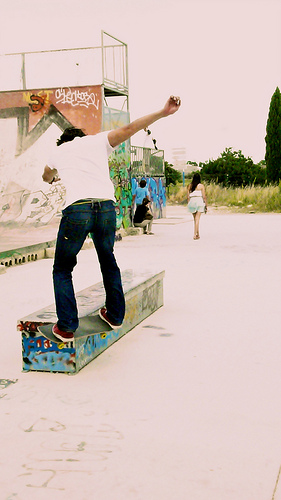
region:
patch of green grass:
[243, 194, 255, 205]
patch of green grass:
[214, 185, 230, 199]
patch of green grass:
[220, 179, 235, 188]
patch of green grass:
[216, 191, 224, 202]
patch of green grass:
[169, 190, 175, 202]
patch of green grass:
[232, 198, 238, 206]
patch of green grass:
[172, 190, 177, 198]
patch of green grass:
[244, 192, 254, 202]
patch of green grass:
[221, 192, 224, 202]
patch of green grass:
[239, 186, 246, 197]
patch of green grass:
[259, 186, 265, 195]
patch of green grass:
[229, 191, 245, 204]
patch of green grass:
[216, 186, 240, 204]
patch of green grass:
[259, 200, 274, 207]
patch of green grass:
[217, 187, 223, 198]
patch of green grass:
[245, 195, 260, 206]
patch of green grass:
[170, 188, 174, 196]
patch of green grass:
[263, 196, 274, 211]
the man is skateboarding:
[38, 90, 185, 340]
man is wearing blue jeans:
[47, 190, 126, 331]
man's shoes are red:
[43, 300, 128, 346]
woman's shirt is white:
[185, 184, 200, 194]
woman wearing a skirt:
[184, 195, 203, 212]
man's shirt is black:
[131, 201, 146, 218]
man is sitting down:
[132, 197, 159, 239]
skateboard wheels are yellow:
[47, 329, 118, 349]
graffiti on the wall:
[109, 161, 178, 228]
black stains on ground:
[138, 318, 175, 345]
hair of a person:
[52, 118, 85, 143]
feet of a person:
[33, 297, 132, 337]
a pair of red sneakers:
[32, 302, 135, 346]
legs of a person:
[43, 218, 138, 344]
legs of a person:
[185, 213, 205, 241]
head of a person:
[187, 173, 201, 183]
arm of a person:
[201, 187, 211, 201]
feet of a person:
[192, 229, 202, 240]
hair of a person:
[191, 170, 199, 186]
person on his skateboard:
[27, 89, 191, 343]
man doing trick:
[24, 76, 181, 352]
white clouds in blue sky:
[20, 14, 56, 42]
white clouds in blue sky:
[210, 68, 241, 115]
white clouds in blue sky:
[231, 32, 263, 52]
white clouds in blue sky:
[94, 8, 138, 44]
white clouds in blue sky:
[165, 15, 226, 53]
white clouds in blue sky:
[205, 47, 260, 106]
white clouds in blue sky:
[187, 109, 219, 141]